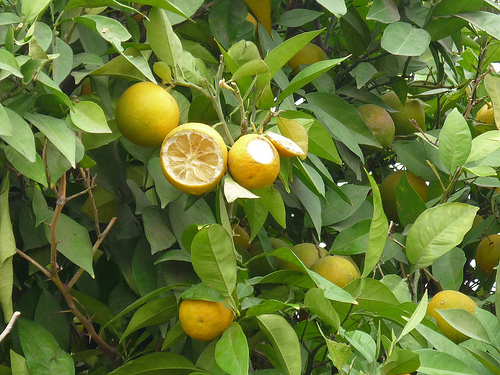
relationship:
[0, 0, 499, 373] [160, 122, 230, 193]
lemon tree with lemon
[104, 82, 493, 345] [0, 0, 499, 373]
lemons in lemon tree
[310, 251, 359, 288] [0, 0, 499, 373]
lemon on lemon tree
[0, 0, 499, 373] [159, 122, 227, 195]
lemon tree with citrus fruit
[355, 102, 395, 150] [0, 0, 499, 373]
lemons on lemon tree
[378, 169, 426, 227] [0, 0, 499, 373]
lemons on lemon tree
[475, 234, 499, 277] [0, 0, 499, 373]
lemons on lemon tree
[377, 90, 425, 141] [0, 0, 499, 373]
lemons on lemon tree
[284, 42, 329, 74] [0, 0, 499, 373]
lemons on lemon tree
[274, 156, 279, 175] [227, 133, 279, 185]
peel of fruit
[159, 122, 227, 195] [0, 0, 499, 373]
citrus fruit on lemon tree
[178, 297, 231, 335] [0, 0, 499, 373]
lemon on lemon tree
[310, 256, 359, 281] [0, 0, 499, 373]
lemon on lemon tree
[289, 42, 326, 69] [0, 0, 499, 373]
lemon on lemon tree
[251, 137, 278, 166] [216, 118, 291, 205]
rind of lemon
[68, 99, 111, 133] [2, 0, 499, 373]
leaf from lemon trees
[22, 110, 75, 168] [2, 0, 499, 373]
leaf from lemon trees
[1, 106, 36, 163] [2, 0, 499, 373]
leaf from lemon trees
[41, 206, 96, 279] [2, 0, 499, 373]
leaf from lemon trees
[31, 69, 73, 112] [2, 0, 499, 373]
leaf from lemon trees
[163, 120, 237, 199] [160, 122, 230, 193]
chunk missing from lemon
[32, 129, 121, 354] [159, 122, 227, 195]
branch has citrus fruit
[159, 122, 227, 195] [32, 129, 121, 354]
citrus fruit on branch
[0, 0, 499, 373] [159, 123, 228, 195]
lemon tree on citrus fruit